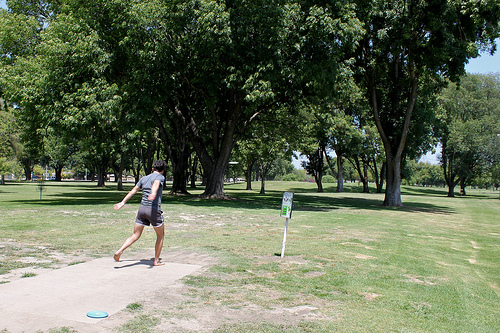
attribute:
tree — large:
[306, 0, 497, 207]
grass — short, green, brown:
[1, 175, 498, 329]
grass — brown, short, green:
[197, 263, 282, 327]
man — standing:
[109, 154, 172, 268]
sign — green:
[278, 190, 293, 219]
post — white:
[280, 220, 292, 256]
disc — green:
[85, 307, 110, 321]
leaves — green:
[365, 0, 497, 97]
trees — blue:
[259, 12, 491, 221]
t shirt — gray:
[136, 170, 166, 205]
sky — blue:
[471, 52, 496, 74]